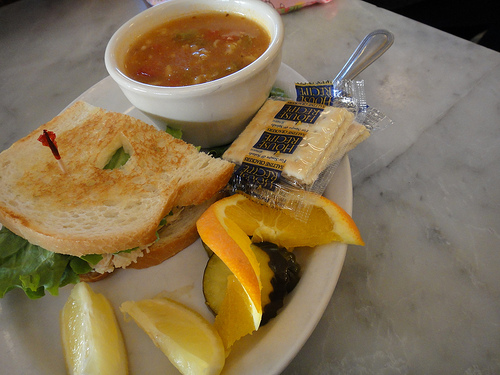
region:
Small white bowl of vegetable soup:
[103, 0, 284, 145]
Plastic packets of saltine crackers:
[222, 75, 359, 205]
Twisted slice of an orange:
[197, 188, 362, 330]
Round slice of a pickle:
[202, 240, 302, 323]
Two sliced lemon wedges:
[45, 275, 233, 372]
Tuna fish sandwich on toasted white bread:
[0, 95, 231, 283]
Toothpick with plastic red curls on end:
[37, 126, 67, 176]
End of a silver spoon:
[330, 25, 395, 89]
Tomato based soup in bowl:
[102, 0, 284, 147]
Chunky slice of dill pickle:
[201, 240, 301, 324]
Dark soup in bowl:
[92, 7, 361, 117]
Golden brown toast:
[22, 104, 179, 261]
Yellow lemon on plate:
[206, 171, 355, 313]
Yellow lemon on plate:
[114, 279, 192, 363]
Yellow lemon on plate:
[55, 282, 132, 364]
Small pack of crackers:
[220, 117, 371, 211]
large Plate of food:
[31, 77, 288, 372]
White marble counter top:
[336, 325, 396, 373]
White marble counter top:
[404, 316, 451, 374]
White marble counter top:
[444, 310, 498, 373]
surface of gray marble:
[1, 4, 496, 372]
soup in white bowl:
[104, 0, 282, 148]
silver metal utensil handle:
[335, 26, 395, 94]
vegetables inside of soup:
[136, 15, 256, 79]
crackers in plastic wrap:
[227, 80, 380, 221]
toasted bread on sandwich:
[0, 98, 233, 278]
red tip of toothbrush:
[39, 128, 73, 175]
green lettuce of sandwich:
[0, 231, 89, 298]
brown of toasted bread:
[27, 111, 174, 209]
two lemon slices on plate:
[61, 282, 221, 373]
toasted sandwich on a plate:
[0, 98, 240, 285]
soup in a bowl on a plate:
[102, 0, 282, 142]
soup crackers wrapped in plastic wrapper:
[220, 75, 380, 217]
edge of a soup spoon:
[330, 25, 397, 90]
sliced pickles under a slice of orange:
[202, 240, 297, 311]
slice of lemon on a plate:
[114, 291, 226, 372]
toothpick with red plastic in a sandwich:
[38, 127, 68, 175]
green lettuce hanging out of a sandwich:
[0, 227, 82, 307]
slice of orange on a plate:
[198, 181, 363, 325]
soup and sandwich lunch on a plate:
[0, 0, 355, 367]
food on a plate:
[0, 0, 396, 372]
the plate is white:
[1, 0, 365, 372]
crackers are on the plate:
[215, 85, 392, 210]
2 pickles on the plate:
[189, 228, 310, 325]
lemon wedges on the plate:
[21, 277, 228, 369]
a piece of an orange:
[158, 181, 375, 318]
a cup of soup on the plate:
[87, 0, 284, 120]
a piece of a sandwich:
[2, 82, 216, 289]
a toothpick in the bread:
[15, 107, 88, 185]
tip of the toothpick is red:
[9, 114, 79, 164]